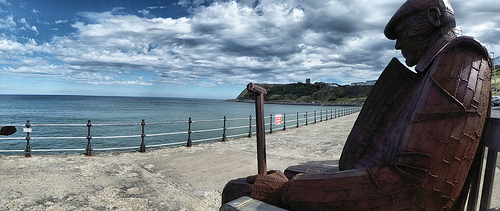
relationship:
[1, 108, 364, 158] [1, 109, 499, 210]
railing next to walkway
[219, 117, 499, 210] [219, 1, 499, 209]
bench of statue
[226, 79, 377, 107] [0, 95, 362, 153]
jetty overlooking water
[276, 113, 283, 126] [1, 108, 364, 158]
sign on railing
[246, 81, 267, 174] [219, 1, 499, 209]
cane on statue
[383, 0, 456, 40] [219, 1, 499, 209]
hat on statue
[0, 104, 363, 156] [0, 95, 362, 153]
gate around water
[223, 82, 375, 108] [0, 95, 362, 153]
rocks near water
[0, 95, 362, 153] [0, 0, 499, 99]
water below sky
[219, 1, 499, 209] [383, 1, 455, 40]
statue wearing hat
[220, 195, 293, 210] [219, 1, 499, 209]
armrest on statue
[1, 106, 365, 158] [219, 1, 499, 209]
railing in front of statue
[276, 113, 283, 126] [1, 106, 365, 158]
sign affixed to railing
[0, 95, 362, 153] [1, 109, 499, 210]
water in front of walkway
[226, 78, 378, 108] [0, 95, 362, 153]
cliff along water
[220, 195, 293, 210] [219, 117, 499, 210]
armrest on bench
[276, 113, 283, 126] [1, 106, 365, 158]
sign on railing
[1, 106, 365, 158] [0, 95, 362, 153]
railing along water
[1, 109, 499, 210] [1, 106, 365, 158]
walkway next to railing